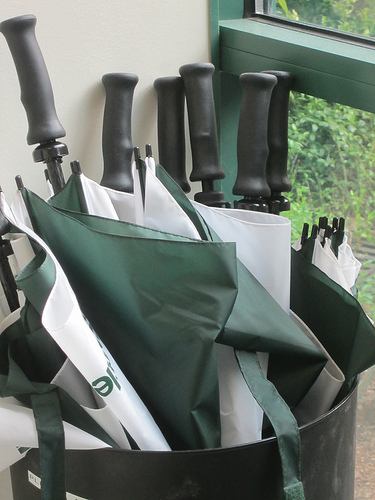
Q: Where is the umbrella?
A: In the black can.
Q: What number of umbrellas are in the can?
A: Six.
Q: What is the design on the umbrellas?
A: White and green.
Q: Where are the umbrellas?
A: Next to the window.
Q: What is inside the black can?
A: Six umbrellas.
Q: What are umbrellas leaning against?
A: A white wall.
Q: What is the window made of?
A: Glass.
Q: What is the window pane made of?
A: Green metal.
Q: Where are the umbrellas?
A: In a bucket.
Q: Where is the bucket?
A: Beside a wall.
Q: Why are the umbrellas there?
A: For storage.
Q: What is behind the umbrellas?
A: Glass.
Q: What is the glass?
A: Windows.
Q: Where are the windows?
A: Next to the umbrellas.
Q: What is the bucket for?
A: Holding umbrellas.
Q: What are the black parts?
A: Handles.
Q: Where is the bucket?
A: Next to the windows.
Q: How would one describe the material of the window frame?
A: Metal.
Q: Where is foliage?
A: Outside the window.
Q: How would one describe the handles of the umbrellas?
A: Dark colored with raised areas on each end.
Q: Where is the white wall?
A: Left of the window.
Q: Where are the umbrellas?
A: In a black barrel.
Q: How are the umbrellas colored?
A: Two tone green and white.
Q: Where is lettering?
A: White part of an umbrella.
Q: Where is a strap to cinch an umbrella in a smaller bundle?
A: Hanging of the edge of black barrel.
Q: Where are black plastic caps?
A: End of spokes on umbrella.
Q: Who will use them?
A: People.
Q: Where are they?
A: In a bucket.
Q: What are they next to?
A: Window.